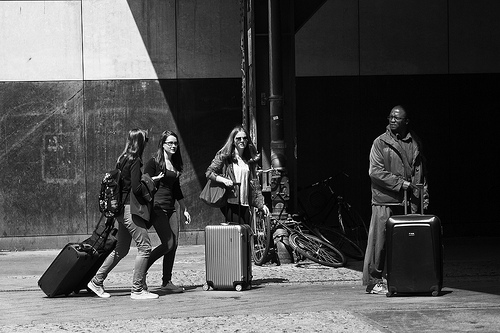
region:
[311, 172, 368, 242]
a leaning bike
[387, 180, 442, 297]
a tall black suitcase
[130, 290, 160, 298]
the shoe of a woman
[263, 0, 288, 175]
part of a black pole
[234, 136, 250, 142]
a woman's dark sunglasses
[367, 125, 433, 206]
a man's dark jacket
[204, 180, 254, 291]
a gray suitcase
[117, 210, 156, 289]
the leg of a woman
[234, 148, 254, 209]
a woman's white shirt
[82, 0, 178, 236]
a woman's black and white wall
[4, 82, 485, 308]
Four people in front of a building.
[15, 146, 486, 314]
3 suitcases with the people.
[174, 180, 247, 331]
Luggage on the ground.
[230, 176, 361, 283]
Bikes by the pole.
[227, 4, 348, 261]
Pole with bikes by it.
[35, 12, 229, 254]
Crack in the wall.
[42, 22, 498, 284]
Wall behind the people.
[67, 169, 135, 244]
Woman with a backpack.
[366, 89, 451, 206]
Man with a jacket.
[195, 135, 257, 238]
Woman with a purse.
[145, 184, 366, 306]
Suitcase on the sidewalk.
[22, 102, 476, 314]
People with suitcases.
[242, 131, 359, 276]
Bicycles against the post.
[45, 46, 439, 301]
Building in the background.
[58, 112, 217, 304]
Woman with a backpack.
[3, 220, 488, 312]
3 suitcases on the ground.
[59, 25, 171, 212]
Lines on the wall.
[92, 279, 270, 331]
Ground in front of the building.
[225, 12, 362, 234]
Pole by the building.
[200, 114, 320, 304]
Woman in the middle of the people.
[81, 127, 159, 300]
woman carrying luggage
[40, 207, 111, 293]
black luggage pulled by woman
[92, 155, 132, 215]
black book bag on woman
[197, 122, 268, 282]
woman carrying large luggage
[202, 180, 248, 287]
rectangle metallic colored luggage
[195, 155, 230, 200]
shoulder bag on woman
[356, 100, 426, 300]
man holding luggage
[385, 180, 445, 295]
black rectangle luggage next to man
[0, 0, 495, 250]
black and white wall behind people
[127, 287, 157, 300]
white shoe on woman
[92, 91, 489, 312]
People in front of the building.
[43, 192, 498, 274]
Suitcases on the ground.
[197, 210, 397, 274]
Bicycles by the pole.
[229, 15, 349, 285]
Post with bicycles on it.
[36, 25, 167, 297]
Line on the wall.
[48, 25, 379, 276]
Walls behind the people.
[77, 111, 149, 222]
Woman with a backpack.